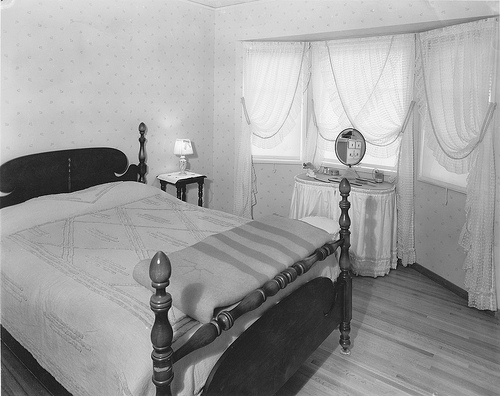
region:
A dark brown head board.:
[0, 123, 145, 209]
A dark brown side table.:
[157, 171, 207, 208]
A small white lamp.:
[173, 137, 194, 177]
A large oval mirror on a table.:
[333, 126, 365, 168]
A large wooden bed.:
[2, 121, 351, 395]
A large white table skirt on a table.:
[290, 172, 397, 280]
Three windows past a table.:
[239, 19, 499, 196]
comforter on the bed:
[56, 210, 163, 272]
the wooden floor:
[371, 325, 423, 370]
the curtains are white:
[428, 41, 498, 126]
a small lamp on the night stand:
[172, 135, 193, 170]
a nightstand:
[171, 165, 202, 196]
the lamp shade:
[175, 141, 190, 152]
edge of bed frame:
[143, 246, 181, 290]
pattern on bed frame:
[141, 275, 183, 340]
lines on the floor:
[393, 315, 476, 383]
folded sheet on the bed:
[188, 224, 268, 276]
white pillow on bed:
[11, 185, 109, 228]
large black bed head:
[11, 139, 138, 198]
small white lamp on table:
[168, 135, 206, 172]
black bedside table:
[161, 165, 218, 205]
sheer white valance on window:
[243, 23, 493, 173]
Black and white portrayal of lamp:
[171, 135, 203, 175]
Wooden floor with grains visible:
[370, 314, 456, 392]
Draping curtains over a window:
[415, 35, 498, 177]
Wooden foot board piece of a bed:
[142, 189, 360, 394]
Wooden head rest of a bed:
[0, 122, 150, 205]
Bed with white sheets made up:
[0, 122, 376, 393]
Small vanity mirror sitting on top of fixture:
[331, 126, 376, 178]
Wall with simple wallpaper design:
[5, 8, 212, 110]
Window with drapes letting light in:
[236, 38, 421, 165]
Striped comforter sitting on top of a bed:
[130, 208, 353, 312]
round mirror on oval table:
[331, 115, 370, 175]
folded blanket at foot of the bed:
[150, 213, 320, 315]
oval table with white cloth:
[287, 163, 404, 288]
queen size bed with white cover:
[9, 129, 394, 366]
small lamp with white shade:
[172, 133, 201, 170]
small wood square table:
[165, 162, 209, 199]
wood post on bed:
[324, 166, 370, 352]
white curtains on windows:
[241, 33, 493, 306]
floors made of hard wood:
[23, 259, 495, 391]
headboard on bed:
[5, 123, 146, 193]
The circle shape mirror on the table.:
[335, 127, 366, 179]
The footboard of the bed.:
[137, 177, 368, 393]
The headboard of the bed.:
[1, 120, 156, 215]